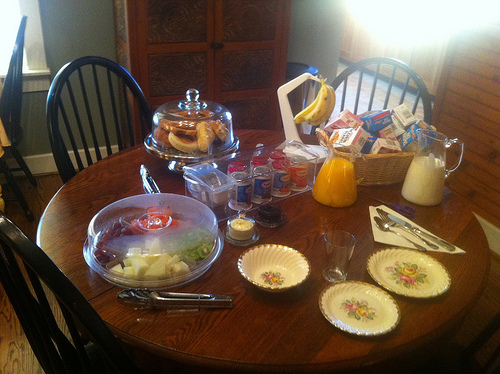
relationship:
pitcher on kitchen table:
[308, 138, 359, 209] [34, 129, 490, 369]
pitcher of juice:
[308, 138, 359, 209] [310, 159, 359, 207]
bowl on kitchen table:
[235, 240, 313, 295] [34, 129, 490, 369]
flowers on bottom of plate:
[338, 293, 382, 324] [317, 279, 403, 339]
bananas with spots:
[291, 79, 341, 132] [321, 94, 329, 103]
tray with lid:
[148, 139, 240, 156] [149, 83, 236, 154]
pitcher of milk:
[396, 123, 466, 210] [402, 159, 447, 206]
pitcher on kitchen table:
[396, 123, 466, 210] [34, 129, 490, 369]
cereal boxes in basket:
[322, 99, 435, 153] [311, 130, 437, 188]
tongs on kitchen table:
[114, 288, 236, 311] [34, 129, 490, 369]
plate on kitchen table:
[317, 279, 403, 339] [34, 129, 490, 369]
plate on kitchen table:
[364, 246, 456, 302] [34, 129, 490, 369]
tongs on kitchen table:
[118, 288, 231, 314] [34, 129, 490, 369]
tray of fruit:
[75, 186, 229, 293] [92, 218, 132, 264]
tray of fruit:
[75, 186, 229, 293] [167, 219, 221, 266]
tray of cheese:
[75, 186, 229, 293] [103, 240, 192, 279]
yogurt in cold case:
[224, 169, 255, 210] [179, 139, 324, 219]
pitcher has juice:
[304, 128, 365, 211] [310, 156, 359, 210]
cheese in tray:
[119, 230, 177, 253] [75, 186, 229, 293]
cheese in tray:
[108, 236, 188, 290] [75, 186, 229, 293]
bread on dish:
[141, 81, 244, 171] [139, 137, 242, 164]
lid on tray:
[85, 190, 215, 277] [78, 213, 223, 288]